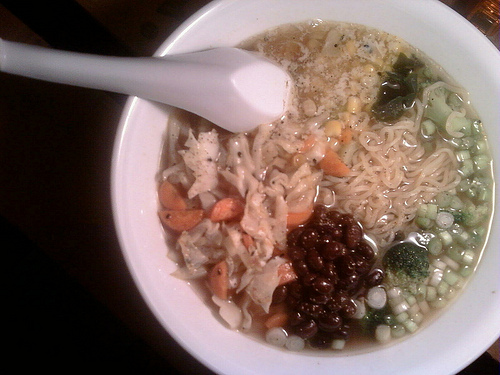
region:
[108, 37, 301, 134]
a long spoon in the bowl.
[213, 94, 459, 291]
Soup in the bowl.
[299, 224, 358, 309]
Black beans in the soup.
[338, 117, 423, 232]
Noodles in the soup.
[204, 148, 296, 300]
White chicken meat in the bowl.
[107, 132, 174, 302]
The bowl is white.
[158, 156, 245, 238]
Carrots in the soup.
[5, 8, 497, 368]
white bowl and utensil against black background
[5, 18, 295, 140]
spoon placed upside down in soup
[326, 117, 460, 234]
tan noodles in loops and coils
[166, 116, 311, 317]
small pieces of carrot and chicken mixed together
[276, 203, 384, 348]
dark red beans on surface of soup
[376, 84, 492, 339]
small slices of scallion with broccoli florets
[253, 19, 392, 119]
foam on top of soup broth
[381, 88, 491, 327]
surface of broth glistening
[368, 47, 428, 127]
dark piece of curled green seaweed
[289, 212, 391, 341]
brwon beans in soup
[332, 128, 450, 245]
noodles in center of bowl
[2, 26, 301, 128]
white spoon in bowl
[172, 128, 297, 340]
meat and carrots in white bowl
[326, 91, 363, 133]
pieces of corn in ramen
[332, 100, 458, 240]
ramen noodles in white bowl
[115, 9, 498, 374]
soup in white bowl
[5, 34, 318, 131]
long spoon in white bowl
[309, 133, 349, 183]
carrot in ramen bowl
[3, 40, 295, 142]
white ladel in bowl of soup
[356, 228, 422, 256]
liquid in white bowl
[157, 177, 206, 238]
carrots bits on soup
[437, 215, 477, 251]
scallions in soup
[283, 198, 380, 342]
black beans in soup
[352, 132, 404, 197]
noodles in soup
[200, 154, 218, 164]
black seasoning on top of soup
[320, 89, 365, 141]
corn bits in soup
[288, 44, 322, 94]
tan material on top of soup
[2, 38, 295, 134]
White spoon sitting in bowl of soup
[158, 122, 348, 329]
Vegetables and chicken in bowl of soup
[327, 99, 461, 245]
Noodles in bowl of soup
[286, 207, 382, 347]
Bunch of black beans in bowl of soup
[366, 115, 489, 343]
Sliced green onions on side of soup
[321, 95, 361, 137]
Corn kernels in the soup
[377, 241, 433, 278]
Cooked broccoli in the soup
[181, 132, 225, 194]
Seasoning sprinkled on top of chicken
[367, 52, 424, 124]
Green vegetable near side of soup bowl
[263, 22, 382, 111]
Fat on top of broth in soup bowl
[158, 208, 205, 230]
small piece of cooked carrot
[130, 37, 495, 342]
food in the bowl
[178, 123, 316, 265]
light food in bowl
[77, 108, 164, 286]
edge of the plate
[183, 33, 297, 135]
top of the handle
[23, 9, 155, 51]
table under the bowl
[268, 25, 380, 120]
liquid in the bowl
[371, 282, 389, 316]
A piece of food on a dish.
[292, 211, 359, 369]
A piece of food on a dish.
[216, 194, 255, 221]
A piece of food on a dish.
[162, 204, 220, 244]
A piece of food on a dish.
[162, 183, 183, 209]
A piece of food on a dish.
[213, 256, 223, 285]
A piece of food on a dish.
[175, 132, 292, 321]
A piece of food on a dish.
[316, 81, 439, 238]
A piece of food on a dish.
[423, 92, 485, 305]
A piece of food on a dish.